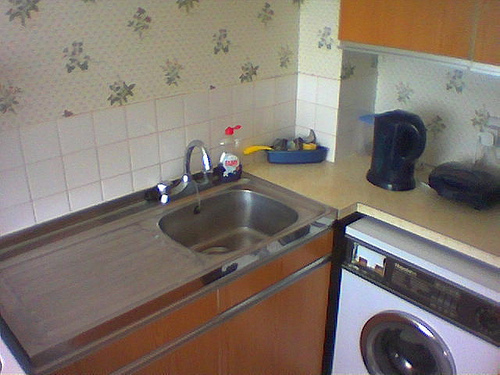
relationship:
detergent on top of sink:
[214, 124, 250, 183] [154, 171, 303, 265]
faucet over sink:
[159, 137, 217, 205] [142, 138, 324, 284]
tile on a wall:
[4, 67, 401, 244] [2, 3, 495, 129]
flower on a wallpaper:
[158, 54, 185, 87] [0, 1, 342, 133]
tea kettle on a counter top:
[364, 104, 431, 195] [241, 144, 499, 278]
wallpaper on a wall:
[0, 0, 296, 125] [2, 1, 301, 238]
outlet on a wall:
[469, 110, 498, 150] [371, 52, 498, 182]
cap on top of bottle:
[220, 123, 243, 137] [209, 120, 248, 185]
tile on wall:
[99, 137, 139, 177] [2, 1, 301, 238]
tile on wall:
[156, 93, 186, 131] [2, 1, 301, 238]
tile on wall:
[122, 102, 160, 144] [2, 1, 301, 238]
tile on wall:
[90, 105, 128, 148] [2, 1, 301, 238]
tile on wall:
[156, 153, 191, 182] [2, 1, 301, 238]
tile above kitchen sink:
[12, 102, 350, 187] [137, 125, 317, 257]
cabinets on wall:
[337, 0, 497, 78] [339, 46, 497, 182]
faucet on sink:
[159, 137, 214, 198] [166, 184, 298, 266]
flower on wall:
[63, 42, 95, 74] [1, 0, 498, 247]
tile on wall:
[96, 149, 125, 169] [0, 9, 338, 205]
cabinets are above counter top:
[337, 0, 497, 78] [241, 144, 499, 278]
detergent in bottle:
[214, 124, 250, 183] [193, 115, 260, 189]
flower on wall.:
[149, 50, 183, 100] [59, 15, 133, 65]